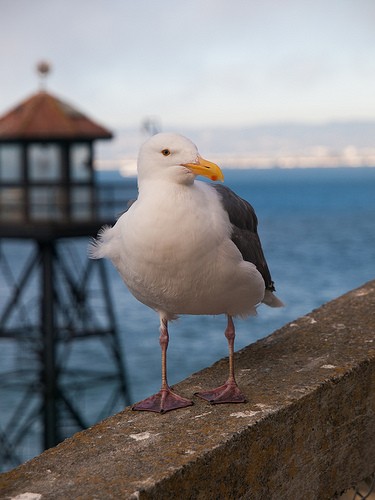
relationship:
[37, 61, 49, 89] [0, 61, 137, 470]
lightening rod on lighthouse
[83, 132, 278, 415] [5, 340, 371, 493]
bird on wall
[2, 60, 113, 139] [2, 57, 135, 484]
top of tower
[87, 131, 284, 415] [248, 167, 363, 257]
seagull near water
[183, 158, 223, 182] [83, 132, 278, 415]
beak of bird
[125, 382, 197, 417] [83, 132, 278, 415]
foot of bird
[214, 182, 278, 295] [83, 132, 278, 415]
feathers on bird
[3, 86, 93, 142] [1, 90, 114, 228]
roof on house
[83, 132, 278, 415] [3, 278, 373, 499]
bird on wall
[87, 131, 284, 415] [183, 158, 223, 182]
seagull on beak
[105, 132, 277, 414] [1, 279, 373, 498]
bird standing on ledge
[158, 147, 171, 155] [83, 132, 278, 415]
eye on bird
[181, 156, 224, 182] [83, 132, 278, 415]
beak on bird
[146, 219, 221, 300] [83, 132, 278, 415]
breast on bird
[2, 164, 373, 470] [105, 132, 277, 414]
water behind bird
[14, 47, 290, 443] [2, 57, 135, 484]
bird standing near tower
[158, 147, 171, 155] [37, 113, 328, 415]
eye on bird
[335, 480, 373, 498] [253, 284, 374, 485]
fence under wall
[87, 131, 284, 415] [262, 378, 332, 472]
seagull on wall